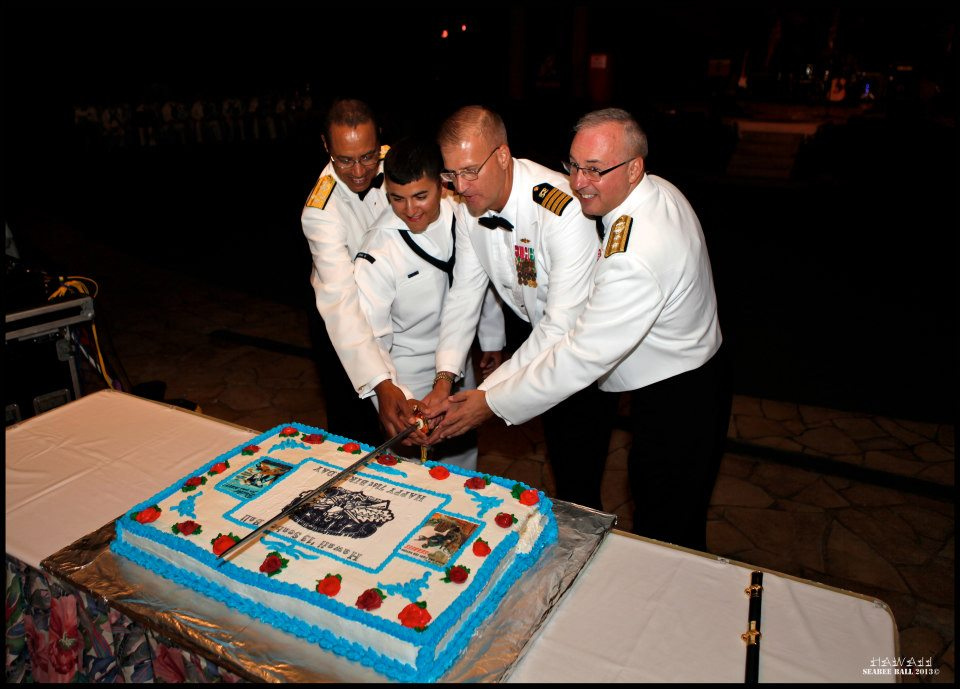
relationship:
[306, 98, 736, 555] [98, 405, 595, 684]
men cut cake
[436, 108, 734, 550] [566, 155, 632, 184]
man wears glasses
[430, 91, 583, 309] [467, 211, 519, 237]
man wears bow tie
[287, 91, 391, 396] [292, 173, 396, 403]
man wears shirt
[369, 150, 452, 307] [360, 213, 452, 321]
man wears sailor uniform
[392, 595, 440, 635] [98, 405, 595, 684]
flower on cake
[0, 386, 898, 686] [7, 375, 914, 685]
table on table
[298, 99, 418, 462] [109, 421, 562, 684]
man standing at cake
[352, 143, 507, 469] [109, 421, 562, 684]
man standing at cake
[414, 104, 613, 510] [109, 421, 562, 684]
man standing at cake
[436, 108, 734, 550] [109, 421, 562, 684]
man standing at cake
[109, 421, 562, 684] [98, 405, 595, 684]
cake on cake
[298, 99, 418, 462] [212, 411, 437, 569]
man holding knife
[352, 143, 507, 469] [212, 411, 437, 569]
man holding knife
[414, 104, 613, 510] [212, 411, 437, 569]
man holding knife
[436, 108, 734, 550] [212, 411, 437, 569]
man holding knife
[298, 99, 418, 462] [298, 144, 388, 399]
man wearing shirt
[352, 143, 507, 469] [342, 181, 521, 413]
man wearing shirts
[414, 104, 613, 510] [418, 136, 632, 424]
man wearing shirts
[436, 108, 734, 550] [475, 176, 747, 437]
man wearing shirts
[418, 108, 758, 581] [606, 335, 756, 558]
man wearing pants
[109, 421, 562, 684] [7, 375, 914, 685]
cake on table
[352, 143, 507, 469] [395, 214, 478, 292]
man wearing tie